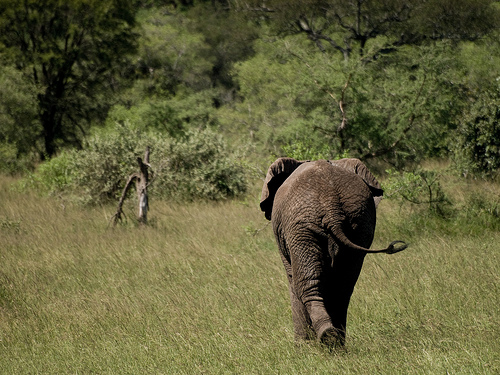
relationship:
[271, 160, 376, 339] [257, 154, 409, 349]
elephant`s skin of elephant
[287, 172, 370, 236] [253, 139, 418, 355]
butt of elephant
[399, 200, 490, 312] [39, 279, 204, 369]
grass blowing ground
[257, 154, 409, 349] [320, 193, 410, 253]
elephant swinging tail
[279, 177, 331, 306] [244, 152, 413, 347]
wrinkled skin of elephant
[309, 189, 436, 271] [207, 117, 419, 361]
tail of elephant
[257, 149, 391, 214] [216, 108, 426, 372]
ears of elephant